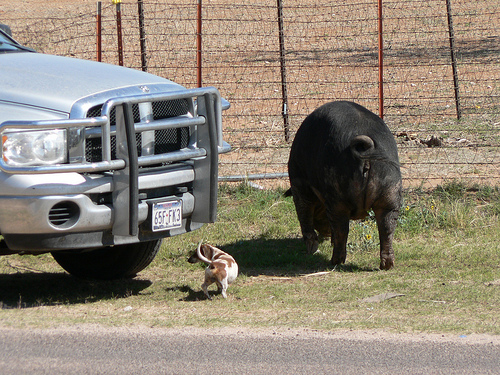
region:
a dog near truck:
[165, 196, 245, 347]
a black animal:
[262, 46, 456, 368]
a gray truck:
[0, 35, 251, 232]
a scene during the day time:
[15, 8, 493, 323]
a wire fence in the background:
[69, 8, 497, 148]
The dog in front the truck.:
[181, 241, 251, 303]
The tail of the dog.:
[194, 240, 212, 260]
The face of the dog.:
[181, 242, 212, 260]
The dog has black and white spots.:
[179, 241, 253, 306]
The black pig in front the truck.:
[281, 85, 437, 256]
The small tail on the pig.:
[352, 126, 377, 151]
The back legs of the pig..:
[325, 217, 416, 278]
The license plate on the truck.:
[146, 185, 203, 236]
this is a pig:
[263, 71, 418, 292]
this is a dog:
[183, 215, 267, 327]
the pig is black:
[258, 62, 443, 282]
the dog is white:
[175, 225, 247, 307]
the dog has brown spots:
[183, 227, 240, 318]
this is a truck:
[0, 23, 270, 315]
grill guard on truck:
[10, 69, 257, 234]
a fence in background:
[68, 3, 490, 174]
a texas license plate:
[135, 182, 192, 239]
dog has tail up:
[196, 237, 224, 273]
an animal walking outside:
[275, 74, 415, 259]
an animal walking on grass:
[261, 83, 408, 343]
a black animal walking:
[307, 102, 408, 270]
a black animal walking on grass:
[292, 90, 381, 305]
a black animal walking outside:
[284, 93, 454, 343]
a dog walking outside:
[168, 241, 253, 320]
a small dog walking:
[157, 230, 264, 330]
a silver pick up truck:
[25, 45, 340, 360]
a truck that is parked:
[22, 4, 328, 371]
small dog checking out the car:
[182, 238, 240, 302]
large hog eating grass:
[278, 101, 406, 273]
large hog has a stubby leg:
[375, 215, 401, 275]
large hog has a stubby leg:
[324, 220, 350, 270]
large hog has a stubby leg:
[295, 211, 320, 263]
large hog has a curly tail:
[348, 128, 377, 163]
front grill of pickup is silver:
[0, 90, 230, 234]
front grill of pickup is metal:
[1, 85, 233, 230]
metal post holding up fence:
[374, 0, 386, 126]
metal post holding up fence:
[274, 1, 292, 143]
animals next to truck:
[0, 20, 402, 300]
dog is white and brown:
[186, 239, 236, 301]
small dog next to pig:
[186, 100, 401, 299]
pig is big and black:
[281, 99, 403, 273]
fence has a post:
[275, 0, 290, 139]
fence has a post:
[378, 2, 385, 117]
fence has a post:
[445, 0, 461, 118]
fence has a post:
[197, 2, 203, 91]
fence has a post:
[116, 2, 124, 63]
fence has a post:
[97, 3, 102, 59]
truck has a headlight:
[2, 129, 68, 164]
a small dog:
[182, 238, 239, 295]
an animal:
[276, 105, 416, 270]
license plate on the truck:
[146, 192, 188, 229]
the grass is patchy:
[427, 242, 487, 304]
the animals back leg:
[373, 219, 403, 263]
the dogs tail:
[192, 243, 216, 267]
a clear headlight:
[11, 120, 66, 175]